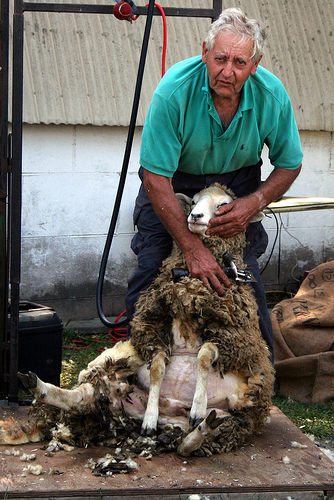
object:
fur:
[129, 232, 274, 457]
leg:
[175, 406, 242, 459]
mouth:
[188, 221, 209, 228]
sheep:
[16, 181, 276, 458]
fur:
[83, 453, 140, 476]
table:
[0, 405, 334, 500]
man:
[124, 6, 304, 400]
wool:
[213, 178, 237, 201]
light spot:
[253, 190, 267, 211]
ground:
[0, 307, 334, 500]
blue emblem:
[240, 143, 245, 150]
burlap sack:
[269, 259, 334, 405]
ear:
[202, 40, 209, 64]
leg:
[129, 277, 173, 438]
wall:
[5, 126, 334, 323]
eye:
[191, 201, 195, 205]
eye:
[217, 202, 228, 208]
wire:
[132, 2, 167, 79]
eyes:
[236, 58, 246, 66]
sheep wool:
[20, 464, 43, 477]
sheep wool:
[145, 453, 153, 460]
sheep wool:
[45, 440, 74, 453]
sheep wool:
[84, 456, 96, 470]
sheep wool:
[290, 441, 308, 449]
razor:
[171, 250, 258, 283]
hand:
[186, 245, 231, 297]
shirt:
[138, 54, 304, 181]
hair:
[204, 6, 268, 65]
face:
[186, 187, 233, 234]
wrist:
[250, 191, 265, 215]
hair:
[21, 463, 44, 479]